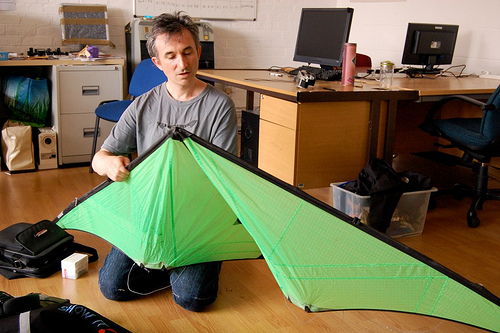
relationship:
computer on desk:
[404, 19, 464, 80] [227, 60, 493, 201]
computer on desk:
[293, 5, 358, 85] [227, 60, 493, 201]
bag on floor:
[0, 216, 100, 278] [2, 164, 499, 329]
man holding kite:
[90, 11, 240, 313] [54, 124, 498, 329]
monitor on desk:
[399, 16, 463, 84] [196, 56, 497, 205]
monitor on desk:
[294, 9, 349, 62] [196, 56, 497, 205]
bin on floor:
[329, 180, 439, 240] [2, 143, 498, 325]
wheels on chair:
[426, 197, 435, 211] [429, 82, 499, 231]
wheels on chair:
[448, 178, 465, 196] [429, 82, 499, 231]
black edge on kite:
[175, 124, 495, 305] [54, 124, 498, 329]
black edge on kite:
[51, 132, 499, 333] [54, 124, 498, 329]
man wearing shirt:
[92, 11, 254, 309] [102, 80, 239, 160]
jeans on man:
[102, 241, 217, 307] [92, 11, 254, 309]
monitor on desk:
[401, 22, 460, 66] [196, 56, 497, 205]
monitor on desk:
[55, 1, 118, 63] [0, 48, 129, 176]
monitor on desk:
[292, 4, 362, 76] [195, 67, 500, 191]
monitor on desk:
[399, 16, 463, 84] [195, 67, 500, 191]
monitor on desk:
[63, 11, 105, 39] [0, 48, 129, 176]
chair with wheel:
[420, 92, 499, 229] [462, 205, 486, 227]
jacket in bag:
[345, 161, 430, 230] [0, 219, 99, 280]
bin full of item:
[327, 180, 436, 240] [342, 155, 427, 232]